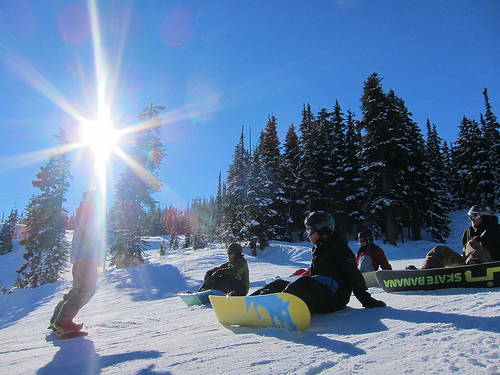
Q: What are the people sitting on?
A: Snow.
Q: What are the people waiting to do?
A: Snowboard.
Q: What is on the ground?
A: Snow.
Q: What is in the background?
A: The sun.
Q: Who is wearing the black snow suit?
A: Man on ground.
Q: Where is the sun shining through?
A: Between the 2 trees.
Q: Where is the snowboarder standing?
A: In glare of sun.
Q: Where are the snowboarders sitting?
A: In the snow.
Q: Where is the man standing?
A: In front of snowboarders.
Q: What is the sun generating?
A: Circle rays.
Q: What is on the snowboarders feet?
A: Snowboard.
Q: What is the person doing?
A: Leaning forward on board.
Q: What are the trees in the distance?
A: Evergreen trees.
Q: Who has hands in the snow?
A: Person with yellow board.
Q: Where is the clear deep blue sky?
A: Over the slope.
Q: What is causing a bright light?
A: The glare from the sun.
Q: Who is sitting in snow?
A: The man.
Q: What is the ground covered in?
A: Snow.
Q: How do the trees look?
A: Covered in snow.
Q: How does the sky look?
A: Blue and clear.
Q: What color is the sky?
A: Blue.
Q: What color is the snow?
A: White.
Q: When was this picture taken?
A: During the day.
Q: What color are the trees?
A: Green.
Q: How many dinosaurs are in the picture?
A: Zero.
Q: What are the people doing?
A: Snowboarding.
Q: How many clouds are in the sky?
A: Zero.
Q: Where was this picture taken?
A: Mountain.